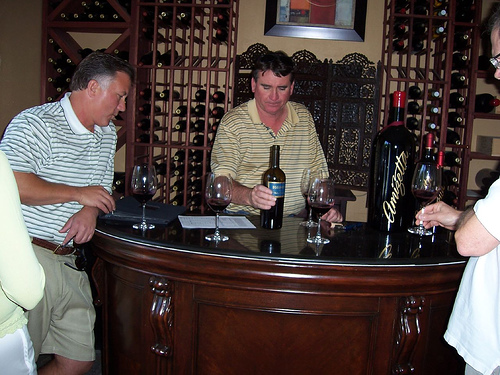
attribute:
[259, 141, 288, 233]
wine — red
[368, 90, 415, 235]
wine — red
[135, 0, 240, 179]
rack — large, wooden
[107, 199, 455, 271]
bar top — black, wooden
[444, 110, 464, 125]
bottle — wine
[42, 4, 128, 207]
wine rack — large, wooden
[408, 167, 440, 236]
glass — wine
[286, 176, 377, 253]
glasses — wine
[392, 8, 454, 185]
wine — red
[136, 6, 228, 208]
wine — red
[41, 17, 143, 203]
wine rack — wooden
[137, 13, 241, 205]
wine rack — wooden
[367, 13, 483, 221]
wine rack — wooden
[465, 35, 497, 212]
wine rack — wooden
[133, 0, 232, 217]
wine rack — wooden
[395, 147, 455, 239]
glass — clear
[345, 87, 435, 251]
bottle — oversized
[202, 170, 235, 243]
glass — clear, stemmed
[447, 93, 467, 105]
bottle — wine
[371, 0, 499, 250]
wine rack — wooden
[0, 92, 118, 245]
shirt — white, striped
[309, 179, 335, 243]
glass — clear, stemmed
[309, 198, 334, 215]
wine — tall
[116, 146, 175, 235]
glass — clear, stemmed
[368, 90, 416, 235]
bottle — Very large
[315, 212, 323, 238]
stem — clear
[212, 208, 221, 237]
stem — clear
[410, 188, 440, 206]
wine — red